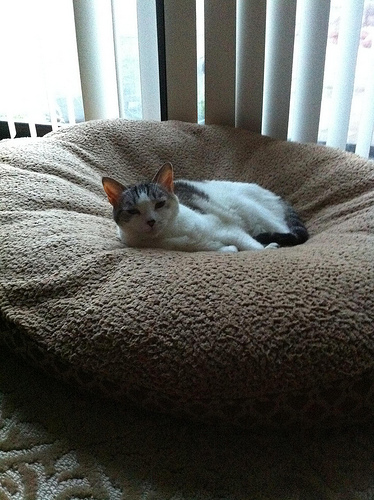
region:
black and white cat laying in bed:
[100, 149, 304, 259]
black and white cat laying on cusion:
[56, 160, 313, 299]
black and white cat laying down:
[39, 133, 313, 275]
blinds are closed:
[65, 9, 373, 128]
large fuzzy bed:
[20, 115, 342, 370]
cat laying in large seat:
[23, 123, 346, 407]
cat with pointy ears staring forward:
[87, 158, 293, 270]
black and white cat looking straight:
[16, 155, 307, 297]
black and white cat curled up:
[12, 146, 319, 292]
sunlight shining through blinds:
[10, 12, 334, 142]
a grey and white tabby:
[80, 168, 317, 265]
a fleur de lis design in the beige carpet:
[4, 429, 95, 498]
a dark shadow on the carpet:
[152, 407, 342, 492]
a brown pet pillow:
[157, 291, 326, 367]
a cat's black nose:
[147, 212, 156, 226]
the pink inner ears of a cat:
[100, 176, 177, 192]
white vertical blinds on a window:
[60, 3, 369, 127]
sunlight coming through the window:
[121, 53, 144, 118]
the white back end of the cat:
[221, 180, 274, 221]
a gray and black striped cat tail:
[280, 205, 304, 247]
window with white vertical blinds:
[1, 7, 372, 150]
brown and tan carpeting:
[5, 406, 260, 497]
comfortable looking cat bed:
[11, 117, 357, 391]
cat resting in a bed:
[83, 147, 321, 270]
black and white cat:
[88, 152, 323, 277]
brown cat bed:
[7, 114, 370, 395]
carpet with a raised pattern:
[0, 411, 154, 497]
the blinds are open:
[0, 3, 373, 159]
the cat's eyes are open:
[78, 146, 330, 260]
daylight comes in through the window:
[2, 6, 372, 161]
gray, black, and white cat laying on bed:
[50, 132, 349, 294]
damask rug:
[7, 359, 332, 496]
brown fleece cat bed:
[37, 259, 346, 412]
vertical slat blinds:
[68, 5, 362, 112]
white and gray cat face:
[89, 160, 186, 252]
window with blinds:
[2, 1, 371, 116]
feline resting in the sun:
[0, 1, 314, 269]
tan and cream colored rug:
[2, 364, 308, 496]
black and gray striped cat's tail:
[251, 190, 314, 251]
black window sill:
[6, 103, 68, 135]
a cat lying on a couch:
[83, 152, 322, 270]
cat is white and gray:
[94, 151, 318, 268]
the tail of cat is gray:
[258, 203, 317, 251]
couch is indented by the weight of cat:
[2, 105, 369, 482]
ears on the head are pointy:
[85, 154, 182, 199]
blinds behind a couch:
[63, 1, 371, 122]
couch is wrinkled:
[3, 125, 106, 303]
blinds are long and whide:
[56, 0, 371, 118]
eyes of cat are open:
[116, 196, 172, 215]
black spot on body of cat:
[176, 175, 216, 214]